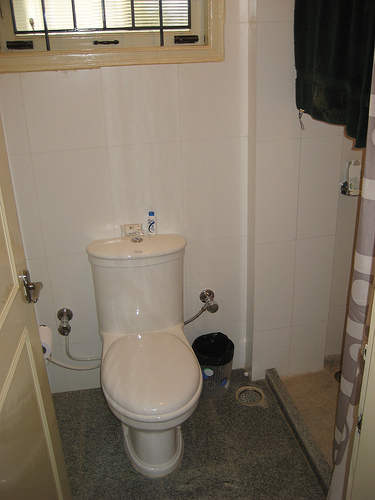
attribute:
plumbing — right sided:
[185, 284, 220, 322]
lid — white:
[130, 320, 238, 445]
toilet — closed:
[83, 211, 208, 404]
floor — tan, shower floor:
[279, 372, 341, 455]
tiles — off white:
[105, 141, 185, 236]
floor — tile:
[50, 365, 326, 498]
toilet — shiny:
[82, 218, 205, 481]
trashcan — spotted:
[190, 332, 232, 398]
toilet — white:
[91, 201, 224, 475]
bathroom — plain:
[4, 4, 370, 498]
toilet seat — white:
[104, 334, 199, 418]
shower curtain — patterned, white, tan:
[313, 59, 374, 498]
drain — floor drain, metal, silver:
[230, 379, 271, 405]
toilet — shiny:
[86, 233, 204, 477]